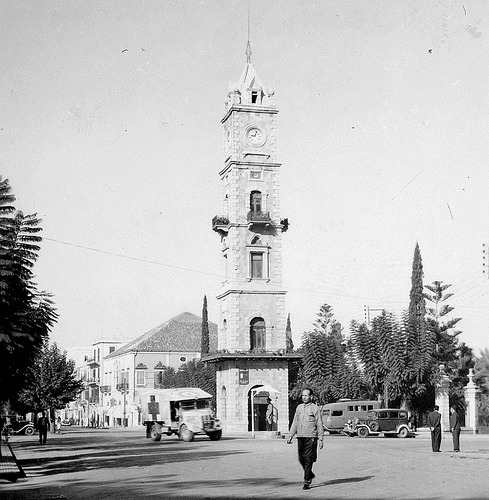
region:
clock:
[237, 107, 274, 154]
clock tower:
[212, 44, 277, 369]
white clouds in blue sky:
[30, 45, 85, 109]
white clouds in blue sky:
[122, 144, 184, 213]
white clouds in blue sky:
[86, 175, 120, 240]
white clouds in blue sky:
[92, 31, 156, 82]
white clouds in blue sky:
[311, 54, 354, 114]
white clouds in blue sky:
[406, 90, 443, 131]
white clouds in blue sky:
[353, 133, 428, 201]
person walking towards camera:
[283, 387, 324, 492]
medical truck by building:
[139, 387, 224, 440]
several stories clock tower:
[201, 5, 303, 440]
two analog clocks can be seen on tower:
[224, 122, 265, 149]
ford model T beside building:
[346, 404, 417, 437]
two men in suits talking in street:
[424, 405, 463, 454]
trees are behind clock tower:
[156, 239, 487, 430]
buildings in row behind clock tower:
[52, 311, 222, 428]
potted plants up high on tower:
[209, 210, 290, 233]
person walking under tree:
[33, 413, 52, 445]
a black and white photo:
[20, 7, 458, 497]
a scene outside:
[7, 6, 487, 497]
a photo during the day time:
[7, 9, 487, 491]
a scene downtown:
[2, 12, 488, 480]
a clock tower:
[176, 17, 332, 444]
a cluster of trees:
[280, 232, 488, 440]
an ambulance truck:
[123, 371, 238, 454]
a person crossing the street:
[273, 378, 345, 496]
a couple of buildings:
[11, 323, 221, 443]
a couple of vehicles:
[308, 389, 421, 443]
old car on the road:
[342, 408, 417, 439]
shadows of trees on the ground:
[1, 430, 301, 497]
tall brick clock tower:
[203, 8, 304, 437]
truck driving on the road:
[140, 385, 222, 440]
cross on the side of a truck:
[147, 393, 161, 419]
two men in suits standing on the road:
[425, 403, 462, 453]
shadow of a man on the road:
[312, 472, 374, 487]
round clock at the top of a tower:
[242, 123, 267, 146]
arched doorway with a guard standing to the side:
[247, 384, 277, 430]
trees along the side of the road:
[0, 176, 83, 419]